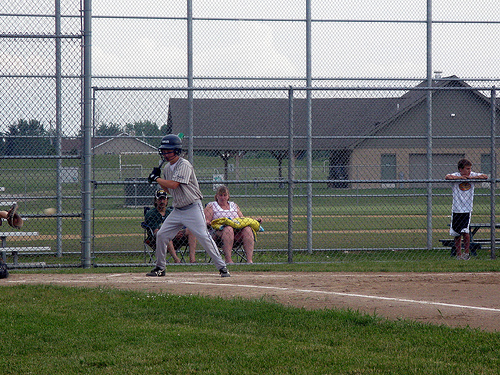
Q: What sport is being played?
A: Baseball.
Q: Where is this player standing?
A: Baseball field.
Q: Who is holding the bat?
A: The batter.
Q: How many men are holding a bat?
A: One.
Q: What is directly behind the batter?
A: Fence.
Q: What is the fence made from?
A: Metal.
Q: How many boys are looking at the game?
A: One.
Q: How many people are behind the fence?
A: Three.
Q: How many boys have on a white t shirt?
A: One.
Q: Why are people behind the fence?
A: So they won't get hit with flying bats and balls.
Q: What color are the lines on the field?
A: White.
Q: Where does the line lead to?
A: First base.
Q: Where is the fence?
A: Behind batter.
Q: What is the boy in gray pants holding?
A: A bat.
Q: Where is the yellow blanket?
A: On the woman.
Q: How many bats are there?
A: One.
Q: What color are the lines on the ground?
A: White.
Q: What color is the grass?
A: Green.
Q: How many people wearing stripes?
A: One.